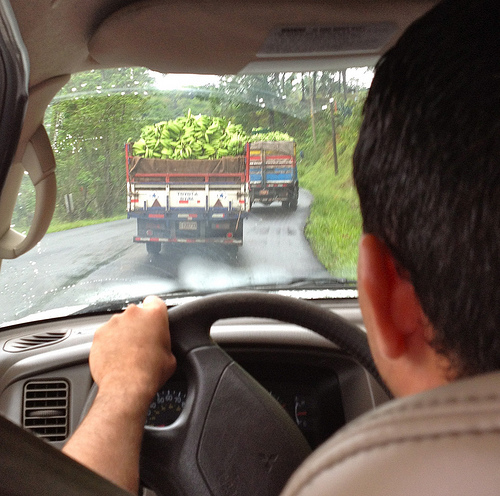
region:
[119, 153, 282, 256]
red and white truck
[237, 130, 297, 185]
red and blue truck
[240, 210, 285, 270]
road is dark grey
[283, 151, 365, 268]
green grass on hill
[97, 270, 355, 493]
steering wheel is black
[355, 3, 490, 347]
man has brown hair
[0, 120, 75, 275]
white handle in car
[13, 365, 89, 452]
grey vent in car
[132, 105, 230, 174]
green bananas in truck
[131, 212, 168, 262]
black wheel on truck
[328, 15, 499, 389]
head of a person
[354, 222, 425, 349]
ear of a person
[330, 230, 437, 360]
an ear of a person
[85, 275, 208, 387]
hand of a person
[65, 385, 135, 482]
arm of a person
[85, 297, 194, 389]
a hand of a person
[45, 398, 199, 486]
an arm of a person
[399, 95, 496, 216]
hair of a person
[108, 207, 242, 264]
back of a truck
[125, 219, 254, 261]
bumper of a truck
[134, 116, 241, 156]
A bundle of bananas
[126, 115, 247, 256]
Car carrying bundle of bananas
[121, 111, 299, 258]
Cars transporting bananas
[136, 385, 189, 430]
Speedometer of a car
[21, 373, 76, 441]
Air vent of a car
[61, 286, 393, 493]
Person holding steering wheel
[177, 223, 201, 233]
License plate on truck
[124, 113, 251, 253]
Truck carrying load of bananas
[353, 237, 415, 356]
Ear of a person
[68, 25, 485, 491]
Person driving a car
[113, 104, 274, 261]
there are bananas in this truck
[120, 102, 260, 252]
there are a lot of bananas in the trailer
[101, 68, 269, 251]
the bananas are green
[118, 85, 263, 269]
the bananas are not ripe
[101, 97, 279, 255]
there are unripe bananas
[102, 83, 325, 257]
there are two trucks hauling bananas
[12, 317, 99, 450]
these are air conditioning vents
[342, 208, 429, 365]
a man's left ear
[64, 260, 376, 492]
this is a steering wheel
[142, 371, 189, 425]
this is a speedometer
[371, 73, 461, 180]
hair of a person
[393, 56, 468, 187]
a hair of a person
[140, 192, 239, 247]
bumper of a truck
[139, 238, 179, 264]
wheel of a truck